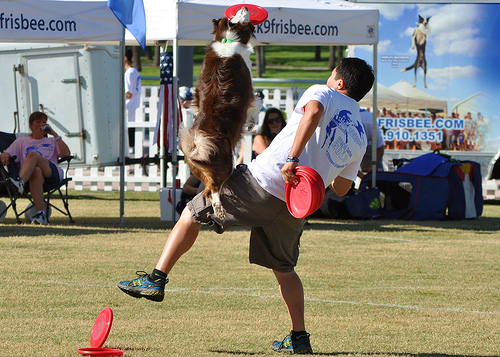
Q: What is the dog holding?
A: Frisbee.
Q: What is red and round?
A: The frisbees.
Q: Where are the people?
A: On the field.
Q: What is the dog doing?
A: Jumping.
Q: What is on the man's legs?
A: It's shorts.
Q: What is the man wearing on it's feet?
A: It's sneakers.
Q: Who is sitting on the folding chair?
A: A woman.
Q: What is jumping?
A: A dog.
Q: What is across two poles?
A: A banner.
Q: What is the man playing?
A: It's frisbee.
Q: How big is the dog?
A: It's medium sized.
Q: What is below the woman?
A: A chair.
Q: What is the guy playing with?
A: A dog.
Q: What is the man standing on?
A: It's grass.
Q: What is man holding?
A: Frisbees.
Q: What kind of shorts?
A: Brown.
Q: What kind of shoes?
A: Tennis.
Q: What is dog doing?
A: Jumping.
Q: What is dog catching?
A: Frisbee.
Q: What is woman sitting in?
A: Chair.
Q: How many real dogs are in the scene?
A: One.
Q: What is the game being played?
A: Frisbee.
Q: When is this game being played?
A: Daytime.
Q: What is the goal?
A: Retrieving frisbee.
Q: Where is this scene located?
A: Fairgrounds.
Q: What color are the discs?
A: Red.